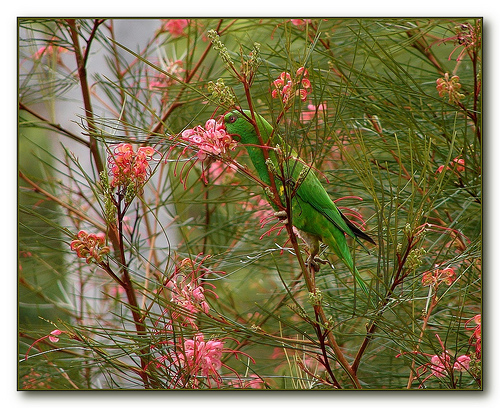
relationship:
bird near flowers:
[218, 118, 372, 267] [77, 54, 397, 271]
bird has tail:
[218, 118, 372, 267] [321, 225, 384, 309]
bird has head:
[218, 118, 372, 267] [217, 115, 254, 148]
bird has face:
[218, 118, 372, 267] [207, 109, 252, 144]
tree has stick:
[32, 35, 360, 333] [65, 51, 99, 167]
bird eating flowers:
[218, 118, 372, 267] [77, 54, 397, 271]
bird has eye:
[215, 108, 377, 313] [221, 111, 240, 122]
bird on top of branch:
[218, 118, 372, 267] [256, 157, 324, 334]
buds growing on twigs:
[205, 30, 240, 66] [215, 34, 284, 177]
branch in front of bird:
[159, 46, 201, 141] [218, 118, 372, 267]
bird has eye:
[218, 118, 372, 267] [221, 111, 240, 122]